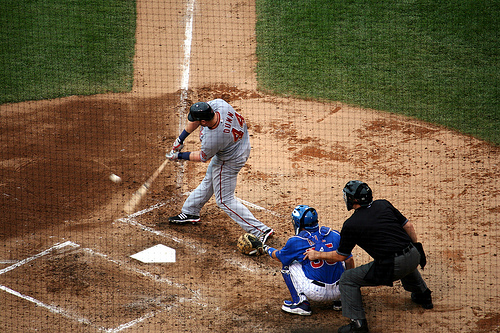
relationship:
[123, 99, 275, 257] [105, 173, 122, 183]
man playing baseball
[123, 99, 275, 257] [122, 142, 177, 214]
man holding bat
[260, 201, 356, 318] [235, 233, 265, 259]
catcher holding baseball glove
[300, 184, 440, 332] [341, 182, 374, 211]
person wearing face mask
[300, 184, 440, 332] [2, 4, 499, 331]
umpire on baseball field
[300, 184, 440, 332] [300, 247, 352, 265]
umpire has arm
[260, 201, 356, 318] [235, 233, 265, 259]
catcher wearing glove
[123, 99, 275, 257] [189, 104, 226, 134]
man has head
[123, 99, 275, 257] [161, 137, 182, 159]
man has hands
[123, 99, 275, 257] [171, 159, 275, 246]
man has legs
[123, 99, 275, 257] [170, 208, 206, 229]
man has foot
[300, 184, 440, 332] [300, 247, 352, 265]
man has arm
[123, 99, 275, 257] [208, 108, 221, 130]
man has neck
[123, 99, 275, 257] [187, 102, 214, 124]
man wearing helmet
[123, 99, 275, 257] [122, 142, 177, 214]
man swinging bat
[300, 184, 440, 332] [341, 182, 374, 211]
man wearing face mask